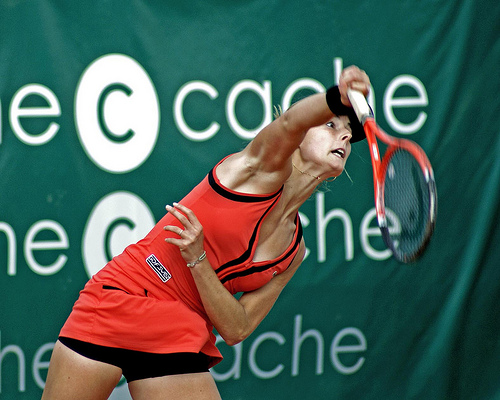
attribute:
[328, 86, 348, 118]
wristband — black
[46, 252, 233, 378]
skirt — orange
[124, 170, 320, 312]
shirt — orange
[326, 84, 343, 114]
wristband — black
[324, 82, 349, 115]
wrist band — black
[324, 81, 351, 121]
sweatband — Black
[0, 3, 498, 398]
sign — advertising, green, white, gray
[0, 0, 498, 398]
tarp — green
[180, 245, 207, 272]
bracelet — silver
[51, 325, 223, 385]
shorts — Tight, black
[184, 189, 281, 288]
shirt — orange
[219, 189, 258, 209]
trim — black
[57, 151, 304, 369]
shirt — black, red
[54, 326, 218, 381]
shorts — black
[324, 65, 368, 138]
wrist band — black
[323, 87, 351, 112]
sweatband — black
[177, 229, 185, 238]
ring — Gold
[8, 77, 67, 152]
e — white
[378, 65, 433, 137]
e — white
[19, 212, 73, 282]
e — white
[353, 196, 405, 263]
e — white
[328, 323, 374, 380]
e — white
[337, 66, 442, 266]
racket — red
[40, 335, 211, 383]
shorts — black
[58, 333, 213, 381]
shorts — black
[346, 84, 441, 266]
racket — black, orange, white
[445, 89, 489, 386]
green backdrop — Green 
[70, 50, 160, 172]
circle — white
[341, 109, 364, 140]
hat — black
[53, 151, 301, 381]
outfit — red